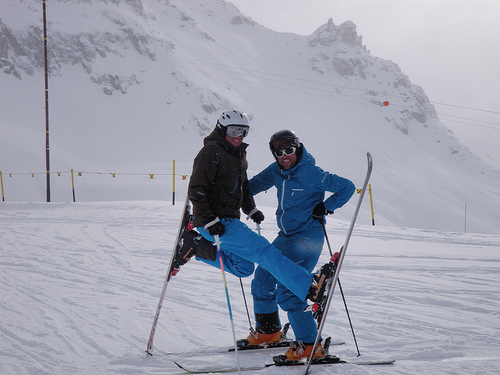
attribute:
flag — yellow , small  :
[56, 171, 62, 177]